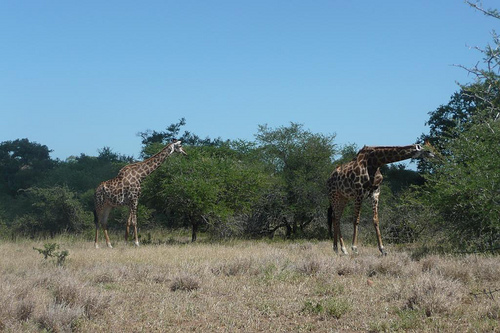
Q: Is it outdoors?
A: Yes, it is outdoors.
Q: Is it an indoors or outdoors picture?
A: It is outdoors.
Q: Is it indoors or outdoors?
A: It is outdoors.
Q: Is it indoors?
A: No, it is outdoors.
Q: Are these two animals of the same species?
A: Yes, all the animals are giraffes.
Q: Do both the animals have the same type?
A: Yes, all the animals are giraffes.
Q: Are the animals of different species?
A: No, all the animals are giraffes.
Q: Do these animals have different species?
A: No, all the animals are giraffes.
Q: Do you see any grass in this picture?
A: Yes, there is grass.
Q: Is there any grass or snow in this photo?
A: Yes, there is grass.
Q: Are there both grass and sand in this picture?
A: No, there is grass but no sand.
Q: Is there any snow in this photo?
A: No, there is no snow.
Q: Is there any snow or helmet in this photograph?
A: No, there are no snow or helmets.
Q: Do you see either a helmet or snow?
A: No, there are no snow or helmets.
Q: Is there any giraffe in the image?
A: Yes, there is a giraffe.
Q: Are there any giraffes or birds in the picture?
A: Yes, there is a giraffe.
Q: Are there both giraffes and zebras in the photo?
A: No, there is a giraffe but no zebras.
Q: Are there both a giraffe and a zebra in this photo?
A: No, there is a giraffe but no zebras.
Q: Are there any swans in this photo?
A: No, there are no swans.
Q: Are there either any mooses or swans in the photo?
A: No, there are no swans or mooses.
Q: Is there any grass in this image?
A: Yes, there is grass.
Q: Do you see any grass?
A: Yes, there is grass.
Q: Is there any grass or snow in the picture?
A: Yes, there is grass.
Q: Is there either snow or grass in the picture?
A: Yes, there is grass.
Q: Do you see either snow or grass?
A: Yes, there is grass.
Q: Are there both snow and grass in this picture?
A: No, there is grass but no snow.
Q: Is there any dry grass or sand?
A: Yes, there is dry grass.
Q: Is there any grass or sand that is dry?
A: Yes, the grass is dry.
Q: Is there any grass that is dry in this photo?
A: Yes, there is dry grass.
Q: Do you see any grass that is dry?
A: Yes, there is grass that is dry.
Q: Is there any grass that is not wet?
A: Yes, there is dry grass.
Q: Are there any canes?
A: No, there are no canes.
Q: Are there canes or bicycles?
A: No, there are no canes or bicycles.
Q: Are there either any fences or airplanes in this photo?
A: No, there are no fences or airplanes.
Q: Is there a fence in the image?
A: No, there are no fences.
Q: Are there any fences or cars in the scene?
A: No, there are no fences or cars.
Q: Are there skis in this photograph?
A: No, there are no skis.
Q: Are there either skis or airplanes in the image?
A: No, there are no skis or airplanes.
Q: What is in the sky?
A: The clouds are in the sky.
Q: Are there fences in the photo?
A: No, there are no fences.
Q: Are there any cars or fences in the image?
A: No, there are no fences or cars.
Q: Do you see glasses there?
A: No, there are no glasses.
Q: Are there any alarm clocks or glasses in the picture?
A: No, there are no glasses or alarm clocks.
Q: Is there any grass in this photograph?
A: Yes, there is grass.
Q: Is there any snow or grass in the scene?
A: Yes, there is grass.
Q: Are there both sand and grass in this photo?
A: No, there is grass but no sand.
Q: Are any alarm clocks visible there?
A: No, there are no alarm clocks.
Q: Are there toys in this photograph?
A: No, there are no toys.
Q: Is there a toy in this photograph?
A: No, there are no toys.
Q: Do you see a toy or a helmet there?
A: No, there are no toys or helmets.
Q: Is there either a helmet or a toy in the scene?
A: No, there are no toys or helmets.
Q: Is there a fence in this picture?
A: No, there are no fences.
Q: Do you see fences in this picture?
A: No, there are no fences.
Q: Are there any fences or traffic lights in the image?
A: No, there are no fences or traffic lights.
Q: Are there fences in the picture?
A: No, there are no fences.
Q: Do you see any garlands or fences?
A: No, there are no fences or garlands.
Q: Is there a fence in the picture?
A: No, there are no fences.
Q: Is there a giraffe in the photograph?
A: Yes, there is a giraffe.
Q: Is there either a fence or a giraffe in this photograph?
A: Yes, there is a giraffe.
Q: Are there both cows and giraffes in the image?
A: No, there is a giraffe but no cows.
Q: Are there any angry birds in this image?
A: No, there are no angry birds.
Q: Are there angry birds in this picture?
A: No, there are no angry birds.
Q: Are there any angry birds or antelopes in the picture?
A: No, there are no angry birds or antelopes.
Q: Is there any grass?
A: Yes, there is grass.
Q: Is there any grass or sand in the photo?
A: Yes, there is grass.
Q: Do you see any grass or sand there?
A: Yes, there is grass.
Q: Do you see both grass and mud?
A: No, there is grass but no mud.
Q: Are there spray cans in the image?
A: No, there are no spray cans.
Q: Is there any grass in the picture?
A: Yes, there is grass.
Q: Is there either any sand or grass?
A: Yes, there is grass.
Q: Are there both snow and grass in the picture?
A: No, there is grass but no snow.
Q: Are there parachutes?
A: No, there are no parachutes.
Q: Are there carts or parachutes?
A: No, there are no parachutes or carts.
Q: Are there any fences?
A: No, there are no fences.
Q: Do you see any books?
A: No, there are no books.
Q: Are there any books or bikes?
A: No, there are no books or bikes.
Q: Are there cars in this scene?
A: No, there are no cars.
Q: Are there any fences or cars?
A: No, there are no cars or fences.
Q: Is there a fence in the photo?
A: No, there are no fences.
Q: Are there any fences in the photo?
A: No, there are no fences.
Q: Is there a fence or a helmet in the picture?
A: No, there are no fences or helmets.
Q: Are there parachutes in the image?
A: No, there are no parachutes.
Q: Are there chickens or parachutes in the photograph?
A: No, there are no parachutes or chickens.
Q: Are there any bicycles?
A: No, there are no bicycles.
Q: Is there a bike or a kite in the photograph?
A: No, there are no bikes or kites.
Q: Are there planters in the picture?
A: No, there are no planters.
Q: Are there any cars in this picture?
A: No, there are no cars.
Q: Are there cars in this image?
A: No, there are no cars.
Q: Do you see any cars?
A: No, there are no cars.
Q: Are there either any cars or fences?
A: No, there are no cars or fences.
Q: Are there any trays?
A: No, there are no trays.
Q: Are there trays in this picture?
A: No, there are no trays.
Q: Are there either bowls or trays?
A: No, there are no trays or bowls.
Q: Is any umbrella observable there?
A: No, there are no umbrellas.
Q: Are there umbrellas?
A: No, there are no umbrellas.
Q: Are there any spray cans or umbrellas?
A: No, there are no umbrellas or spray cans.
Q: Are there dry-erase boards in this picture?
A: No, there are no dry-erase boards.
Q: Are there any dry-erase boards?
A: No, there are no dry-erase boards.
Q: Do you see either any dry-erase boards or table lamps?
A: No, there are no dry-erase boards or table lamps.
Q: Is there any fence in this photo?
A: No, there are no fences.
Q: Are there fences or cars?
A: No, there are no fences or cars.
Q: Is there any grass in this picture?
A: Yes, there is grass.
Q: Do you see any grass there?
A: Yes, there is grass.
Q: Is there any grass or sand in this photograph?
A: Yes, there is grass.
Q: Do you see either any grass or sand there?
A: Yes, there is grass.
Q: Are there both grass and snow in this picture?
A: No, there is grass but no snow.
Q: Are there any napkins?
A: No, there are no napkins.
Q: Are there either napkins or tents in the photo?
A: No, there are no napkins or tents.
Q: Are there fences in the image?
A: No, there are no fences.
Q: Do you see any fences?
A: No, there are no fences.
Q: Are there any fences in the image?
A: No, there are no fences.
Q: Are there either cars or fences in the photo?
A: No, there are no fences or cars.